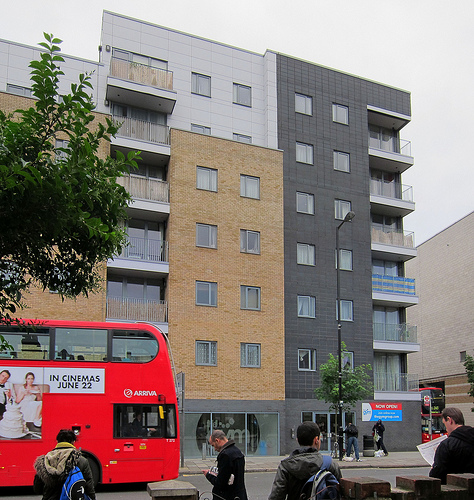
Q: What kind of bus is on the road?
A: Double decker.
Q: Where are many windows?
A: On a building.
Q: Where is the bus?
A: In the street.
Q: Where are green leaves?
A: On a tree.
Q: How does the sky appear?
A: Overcast.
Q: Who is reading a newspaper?
A: Man on right.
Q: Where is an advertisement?
A: On side of the bus.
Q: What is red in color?
A: Bus.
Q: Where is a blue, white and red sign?
A: On side of the building.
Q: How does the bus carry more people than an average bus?
A: Double decker.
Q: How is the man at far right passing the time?
A: Reading.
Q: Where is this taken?
A: A city street.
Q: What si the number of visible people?
A: Six.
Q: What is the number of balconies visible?
A: Eleven.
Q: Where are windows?
A: On a building.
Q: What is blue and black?
A: A bag.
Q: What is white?
A: Sky.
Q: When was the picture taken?
A: Daytime.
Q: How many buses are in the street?
A: One.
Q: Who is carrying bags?
A: Two people.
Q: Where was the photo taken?
A: On a city street.